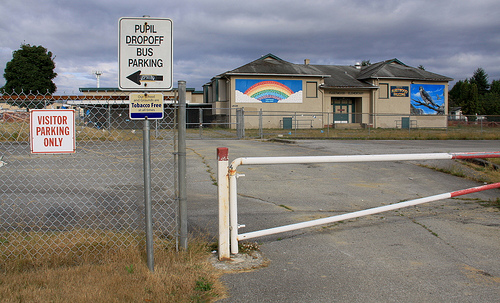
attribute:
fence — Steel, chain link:
[7, 82, 194, 267]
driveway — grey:
[351, 255, 454, 300]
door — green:
[333, 101, 350, 123]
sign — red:
[333, 104, 350, 113]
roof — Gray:
[230, 53, 452, 80]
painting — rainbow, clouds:
[229, 70, 313, 124]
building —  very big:
[77, 52, 453, 137]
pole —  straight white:
[216, 146, 230, 259]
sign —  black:
[119, 14, 169, 89]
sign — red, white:
[27, 104, 81, 157]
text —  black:
[125, 22, 165, 68]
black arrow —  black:
[125, 69, 163, 85]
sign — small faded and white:
[125, 89, 162, 119]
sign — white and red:
[28, 109, 76, 158]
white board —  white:
[114, 15, 175, 95]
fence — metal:
[70, 167, 120, 259]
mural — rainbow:
[304, 72, 314, 148]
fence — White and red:
[299, 148, 449, 189]